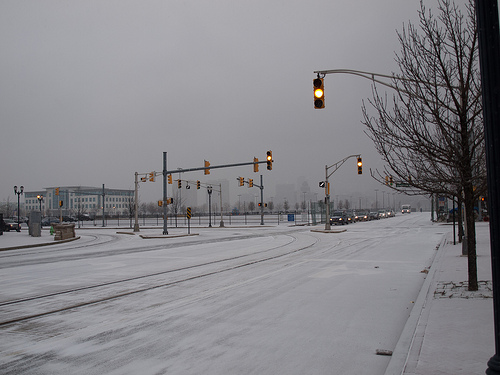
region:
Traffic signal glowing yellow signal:
[307, 65, 333, 129]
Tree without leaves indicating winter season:
[374, 21, 494, 308]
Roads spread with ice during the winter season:
[14, 253, 384, 370]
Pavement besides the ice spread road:
[4, 310, 498, 360]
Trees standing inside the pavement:
[431, 45, 492, 361]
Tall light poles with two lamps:
[4, 183, 78, 250]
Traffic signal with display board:
[131, 142, 286, 233]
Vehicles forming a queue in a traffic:
[331, 195, 416, 265]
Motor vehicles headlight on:
[322, 201, 424, 231]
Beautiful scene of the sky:
[125, 69, 324, 304]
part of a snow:
[231, 318, 253, 355]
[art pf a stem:
[468, 254, 484, 293]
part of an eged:
[404, 286, 424, 320]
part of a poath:
[446, 289, 474, 328]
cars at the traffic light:
[323, 203, 404, 230]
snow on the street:
[163, 259, 345, 371]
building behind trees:
[24, 173, 135, 215]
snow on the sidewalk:
[411, 290, 488, 370]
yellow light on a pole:
[308, 74, 332, 108]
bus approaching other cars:
[398, 198, 417, 214]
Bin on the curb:
[51, 212, 81, 242]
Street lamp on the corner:
[9, 183, 29, 232]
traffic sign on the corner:
[181, 200, 194, 237]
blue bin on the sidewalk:
[282, 205, 300, 230]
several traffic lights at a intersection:
[108, 61, 410, 245]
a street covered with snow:
[0, 245, 351, 362]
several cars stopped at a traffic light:
[323, 203, 400, 236]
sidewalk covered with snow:
[426, 220, 486, 373]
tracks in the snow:
[118, 236, 348, 327]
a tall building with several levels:
[10, 171, 137, 233]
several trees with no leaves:
[421, 42, 471, 312]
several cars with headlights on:
[325, 204, 412, 234]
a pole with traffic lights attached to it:
[145, 145, 292, 245]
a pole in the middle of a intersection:
[307, 142, 365, 245]